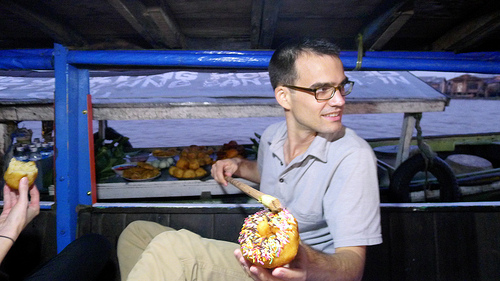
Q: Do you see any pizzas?
A: No, there are no pizzas.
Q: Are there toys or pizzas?
A: No, there are no pizzas or toys.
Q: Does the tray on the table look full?
A: Yes, the tray is full.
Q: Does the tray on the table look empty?
A: No, the tray is full.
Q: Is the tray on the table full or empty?
A: The tray is full.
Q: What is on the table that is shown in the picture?
A: The tray is on the table.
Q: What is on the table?
A: The tray is on the table.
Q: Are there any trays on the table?
A: Yes, there is a tray on the table.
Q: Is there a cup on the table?
A: No, there is a tray on the table.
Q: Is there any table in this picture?
A: Yes, there is a table.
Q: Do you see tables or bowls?
A: Yes, there is a table.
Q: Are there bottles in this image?
A: No, there are no bottles.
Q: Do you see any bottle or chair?
A: No, there are no bottles or chairs.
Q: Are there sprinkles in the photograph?
A: Yes, there are sprinkles.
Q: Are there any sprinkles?
A: Yes, there are sprinkles.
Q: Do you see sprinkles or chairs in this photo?
A: Yes, there are sprinkles.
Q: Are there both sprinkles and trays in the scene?
A: Yes, there are both sprinkles and a tray.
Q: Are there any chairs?
A: No, there are no chairs.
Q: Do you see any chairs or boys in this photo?
A: No, there are no chairs or boys.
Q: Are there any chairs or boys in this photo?
A: No, there are no chairs or boys.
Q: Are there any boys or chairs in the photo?
A: No, there are no chairs or boys.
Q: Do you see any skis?
A: No, there are no skis.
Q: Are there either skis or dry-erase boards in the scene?
A: No, there are no skis or dry-erase boards.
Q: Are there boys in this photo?
A: No, there are no boys.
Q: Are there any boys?
A: No, there are no boys.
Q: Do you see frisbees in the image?
A: No, there are no frisbees.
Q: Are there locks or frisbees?
A: No, there are no frisbees or locks.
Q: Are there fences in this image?
A: No, there are no fences.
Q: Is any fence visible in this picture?
A: No, there are no fences.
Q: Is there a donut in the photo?
A: Yes, there is a donut.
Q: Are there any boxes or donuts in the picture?
A: Yes, there is a donut.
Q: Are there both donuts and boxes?
A: No, there is a donut but no boxes.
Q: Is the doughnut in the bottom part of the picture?
A: Yes, the doughnut is in the bottom of the image.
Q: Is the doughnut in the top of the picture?
A: No, the doughnut is in the bottom of the image.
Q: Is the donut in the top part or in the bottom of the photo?
A: The donut is in the bottom of the image.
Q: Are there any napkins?
A: No, there are no napkins.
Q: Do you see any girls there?
A: No, there are no girls.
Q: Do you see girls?
A: No, there are no girls.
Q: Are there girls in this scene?
A: No, there are no girls.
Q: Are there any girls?
A: No, there are no girls.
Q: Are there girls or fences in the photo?
A: No, there are no girls or fences.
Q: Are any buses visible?
A: No, there are no buses.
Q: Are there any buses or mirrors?
A: No, there are no buses or mirrors.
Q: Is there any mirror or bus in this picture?
A: No, there are no buses or mirrors.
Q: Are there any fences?
A: No, there are no fences.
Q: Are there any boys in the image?
A: No, there are no boys.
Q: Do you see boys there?
A: No, there are no boys.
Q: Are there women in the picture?
A: No, there are no women.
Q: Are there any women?
A: No, there are no women.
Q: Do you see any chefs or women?
A: No, there are no women or chefs.